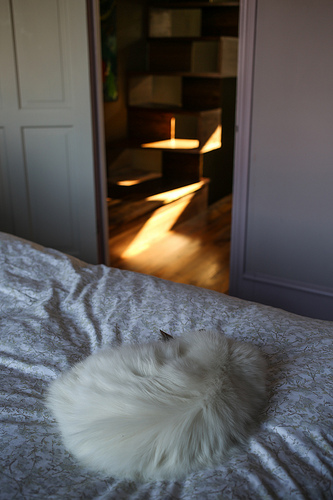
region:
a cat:
[50, 300, 294, 476]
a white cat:
[40, 293, 322, 488]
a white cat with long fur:
[32, 310, 294, 498]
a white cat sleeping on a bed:
[34, 305, 304, 498]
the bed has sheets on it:
[8, 244, 326, 495]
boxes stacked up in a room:
[105, 6, 241, 212]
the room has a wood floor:
[107, 166, 246, 301]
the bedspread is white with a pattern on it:
[18, 249, 296, 492]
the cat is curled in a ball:
[54, 284, 320, 483]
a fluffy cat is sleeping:
[32, 284, 290, 497]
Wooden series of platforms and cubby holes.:
[102, 4, 219, 224]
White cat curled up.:
[40, 294, 296, 490]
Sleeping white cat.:
[35, 310, 277, 493]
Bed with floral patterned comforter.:
[5, 220, 331, 487]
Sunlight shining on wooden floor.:
[108, 90, 234, 262]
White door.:
[13, 0, 140, 264]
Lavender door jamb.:
[170, 0, 278, 299]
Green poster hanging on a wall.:
[97, 0, 135, 105]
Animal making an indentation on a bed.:
[16, 284, 299, 492]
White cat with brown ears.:
[45, 315, 293, 486]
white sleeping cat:
[38, 325, 282, 478]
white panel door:
[2, 2, 108, 272]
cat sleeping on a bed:
[6, 246, 316, 479]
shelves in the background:
[100, 0, 246, 222]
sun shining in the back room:
[103, 87, 245, 297]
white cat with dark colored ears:
[27, 319, 293, 479]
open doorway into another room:
[40, 0, 291, 303]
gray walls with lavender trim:
[238, 2, 332, 312]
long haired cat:
[32, 312, 279, 492]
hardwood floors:
[100, 131, 243, 310]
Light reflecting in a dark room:
[122, 181, 210, 261]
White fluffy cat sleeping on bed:
[54, 319, 279, 481]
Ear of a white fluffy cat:
[156, 321, 176, 344]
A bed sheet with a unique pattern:
[4, 228, 332, 495]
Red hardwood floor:
[99, 156, 233, 296]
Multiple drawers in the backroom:
[118, 7, 234, 185]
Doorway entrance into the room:
[80, 0, 248, 293]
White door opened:
[5, 0, 117, 267]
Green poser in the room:
[92, 0, 122, 100]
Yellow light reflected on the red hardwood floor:
[122, 115, 225, 272]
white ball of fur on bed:
[43, 322, 278, 473]